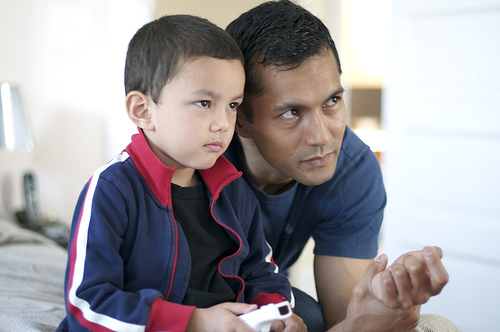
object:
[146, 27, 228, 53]
brunette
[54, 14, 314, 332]
child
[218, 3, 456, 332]
man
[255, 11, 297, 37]
black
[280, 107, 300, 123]
eye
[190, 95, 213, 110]
eye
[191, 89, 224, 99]
eyebrow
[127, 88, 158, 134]
ear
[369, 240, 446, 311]
hand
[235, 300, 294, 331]
wii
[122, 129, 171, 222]
blue and red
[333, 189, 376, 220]
blue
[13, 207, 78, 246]
handset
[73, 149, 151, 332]
stripe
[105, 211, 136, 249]
blue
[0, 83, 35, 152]
lampshade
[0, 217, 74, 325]
bed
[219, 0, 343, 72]
hair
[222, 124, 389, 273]
shirt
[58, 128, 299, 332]
jacket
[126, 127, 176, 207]
red trim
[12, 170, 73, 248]
telephone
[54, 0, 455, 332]
man and boy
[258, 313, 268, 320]
white